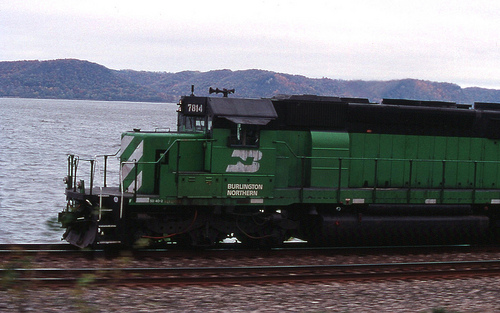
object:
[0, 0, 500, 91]
sky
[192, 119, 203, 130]
window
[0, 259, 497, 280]
tracks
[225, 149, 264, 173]
sign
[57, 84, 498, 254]
train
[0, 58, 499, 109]
hills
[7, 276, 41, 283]
grayish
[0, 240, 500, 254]
tracks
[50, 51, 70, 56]
white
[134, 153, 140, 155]
white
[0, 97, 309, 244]
lake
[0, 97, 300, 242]
calm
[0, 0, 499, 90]
cloudy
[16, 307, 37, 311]
stones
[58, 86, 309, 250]
head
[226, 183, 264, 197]
sign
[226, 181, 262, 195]
writing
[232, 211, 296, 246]
wheels